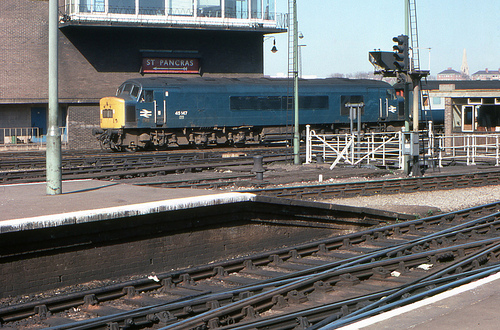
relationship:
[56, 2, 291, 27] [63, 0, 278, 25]
wire around windows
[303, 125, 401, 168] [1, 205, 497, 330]
rails near track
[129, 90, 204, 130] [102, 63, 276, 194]
door on engine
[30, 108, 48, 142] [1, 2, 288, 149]
door on building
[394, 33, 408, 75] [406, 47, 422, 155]
light on pole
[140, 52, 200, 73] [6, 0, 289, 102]
sign on building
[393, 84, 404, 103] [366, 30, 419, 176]
street sign on pole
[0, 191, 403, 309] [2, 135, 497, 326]
hole in ground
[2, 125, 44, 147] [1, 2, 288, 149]
railing in front of building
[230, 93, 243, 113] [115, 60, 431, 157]
window on side of train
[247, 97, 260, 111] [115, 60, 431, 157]
window on side of train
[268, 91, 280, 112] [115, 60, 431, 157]
window on side of train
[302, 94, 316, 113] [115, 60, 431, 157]
window on side of train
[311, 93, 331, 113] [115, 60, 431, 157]
window on side of train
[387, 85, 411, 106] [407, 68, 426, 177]
traffic signal on post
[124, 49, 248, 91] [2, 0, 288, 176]
sign on building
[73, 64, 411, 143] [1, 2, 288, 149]
train at building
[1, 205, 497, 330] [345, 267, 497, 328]
track beside platform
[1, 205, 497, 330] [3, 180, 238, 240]
track beside platform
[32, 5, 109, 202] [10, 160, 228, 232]
pole on platform